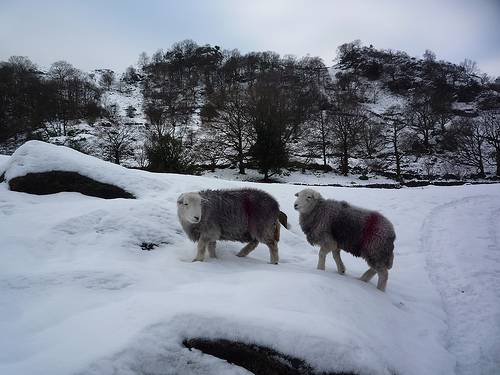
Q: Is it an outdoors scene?
A: Yes, it is outdoors.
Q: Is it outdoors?
A: Yes, it is outdoors.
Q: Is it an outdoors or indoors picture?
A: It is outdoors.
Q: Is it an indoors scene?
A: No, it is outdoors.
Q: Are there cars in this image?
A: No, there are no cars.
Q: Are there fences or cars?
A: No, there are no cars or fences.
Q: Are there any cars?
A: No, there are no cars.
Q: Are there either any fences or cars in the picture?
A: No, there are no cars or fences.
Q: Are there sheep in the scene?
A: Yes, there is a sheep.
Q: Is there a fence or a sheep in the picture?
A: Yes, there is a sheep.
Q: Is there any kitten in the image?
A: No, there are no kittens.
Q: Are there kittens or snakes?
A: No, there are no kittens or snakes.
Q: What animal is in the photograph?
A: The animal is a sheep.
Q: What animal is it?
A: The animal is a sheep.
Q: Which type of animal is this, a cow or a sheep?
A: That is a sheep.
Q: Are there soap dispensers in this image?
A: No, there are no soap dispensers.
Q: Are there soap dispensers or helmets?
A: No, there are no soap dispensers or helmets.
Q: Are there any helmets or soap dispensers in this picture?
A: No, there are no soap dispensers or helmets.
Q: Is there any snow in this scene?
A: Yes, there is snow.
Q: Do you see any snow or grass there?
A: Yes, there is snow.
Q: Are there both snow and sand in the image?
A: No, there is snow but no sand.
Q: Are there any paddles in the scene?
A: No, there are no paddles.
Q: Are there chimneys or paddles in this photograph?
A: No, there are no paddles or chimneys.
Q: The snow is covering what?
A: The snow is covering the hillside.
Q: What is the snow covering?
A: The snow is covering the hillside.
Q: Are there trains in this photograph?
A: No, there are no trains.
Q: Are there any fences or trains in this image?
A: No, there are no trains or fences.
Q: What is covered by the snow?
A: The hill side is covered by the snow.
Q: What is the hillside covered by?
A: The hillside is covered by the snow.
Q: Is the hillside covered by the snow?
A: Yes, the hillside is covered by the snow.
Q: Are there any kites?
A: No, there are no kites.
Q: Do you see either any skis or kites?
A: No, there are no kites or skis.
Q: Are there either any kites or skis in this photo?
A: No, there are no kites or skis.